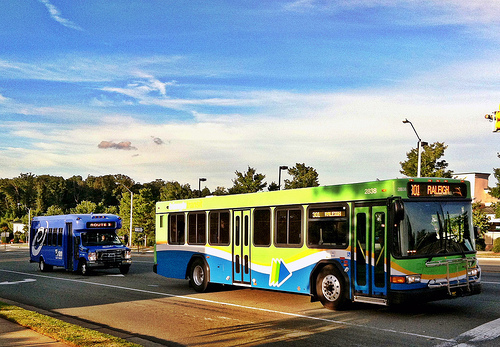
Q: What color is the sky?
A: Blue.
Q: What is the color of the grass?
A: Green.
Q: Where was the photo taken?
A: From the sidewalk of a city street.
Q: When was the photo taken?
A: Daytime.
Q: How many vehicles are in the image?
A: Two.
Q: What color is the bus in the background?
A: Blue.